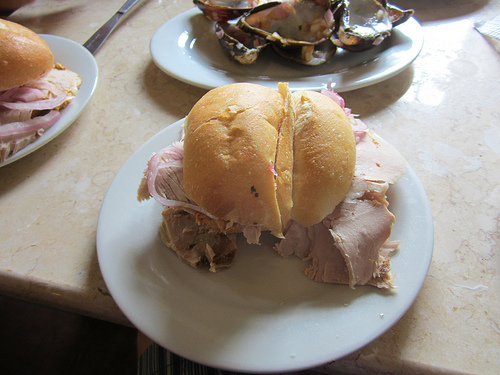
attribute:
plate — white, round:
[92, 115, 437, 373]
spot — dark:
[243, 183, 264, 199]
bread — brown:
[184, 80, 359, 240]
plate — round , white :
[151, 3, 425, 90]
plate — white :
[3, 30, 99, 169]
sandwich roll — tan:
[184, 80, 360, 231]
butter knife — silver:
[83, 0, 144, 56]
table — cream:
[0, 2, 499, 371]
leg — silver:
[130, 324, 178, 373]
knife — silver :
[81, 0, 153, 56]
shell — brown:
[209, 6, 376, 67]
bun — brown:
[188, 71, 376, 258]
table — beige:
[46, 6, 496, 231]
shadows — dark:
[177, 25, 407, 90]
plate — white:
[120, 131, 478, 359]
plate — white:
[13, 18, 114, 194]